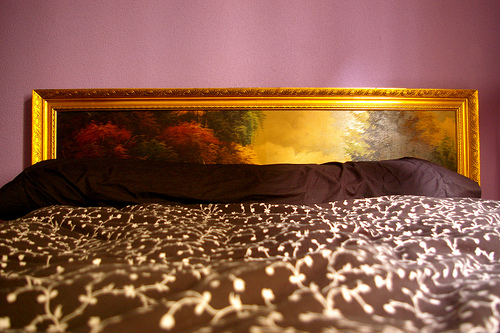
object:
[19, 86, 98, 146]
frame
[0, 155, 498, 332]
bed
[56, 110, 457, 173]
photo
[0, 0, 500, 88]
wall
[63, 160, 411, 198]
pillow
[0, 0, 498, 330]
bedroom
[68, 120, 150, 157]
bush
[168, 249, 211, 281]
design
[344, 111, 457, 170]
tree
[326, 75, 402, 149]
light